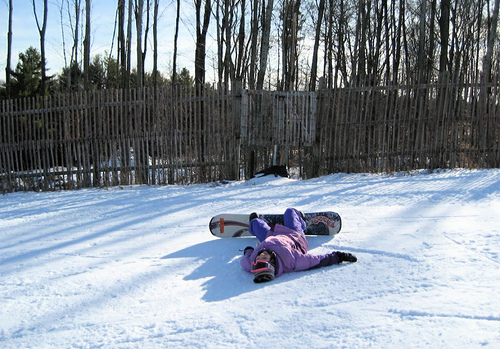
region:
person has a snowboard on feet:
[201, 196, 362, 286]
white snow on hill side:
[120, 249, 134, 270]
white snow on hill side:
[421, 276, 496, 334]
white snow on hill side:
[387, 203, 415, 217]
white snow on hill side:
[45, 278, 72, 299]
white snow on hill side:
[377, 309, 425, 343]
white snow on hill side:
[400, 209, 432, 241]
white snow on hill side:
[122, 292, 146, 323]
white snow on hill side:
[284, 305, 311, 333]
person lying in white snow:
[180, 211, 372, 283]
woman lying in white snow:
[182, 192, 354, 282]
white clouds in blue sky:
[32, 20, 58, 44]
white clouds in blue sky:
[181, 20, 208, 53]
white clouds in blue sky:
[272, 9, 303, 51]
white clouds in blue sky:
[368, 19, 401, 56]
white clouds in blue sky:
[445, 5, 475, 28]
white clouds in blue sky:
[275, 31, 292, 53]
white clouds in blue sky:
[281, 25, 324, 68]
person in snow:
[210, 201, 353, 276]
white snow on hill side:
[17, 248, 49, 293]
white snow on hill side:
[387, 281, 429, 328]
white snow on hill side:
[274, 285, 301, 321]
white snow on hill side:
[424, 190, 488, 243]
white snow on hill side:
[366, 190, 406, 224]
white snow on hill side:
[122, 222, 171, 256]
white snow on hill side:
[40, 229, 108, 261]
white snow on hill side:
[98, 237, 140, 262]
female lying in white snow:
[193, 195, 350, 276]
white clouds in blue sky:
[13, 13, 45, 43]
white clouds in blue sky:
[42, 9, 82, 46]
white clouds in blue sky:
[113, 11, 193, 53]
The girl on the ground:
[236, 206, 357, 321]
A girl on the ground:
[226, 211, 357, 294]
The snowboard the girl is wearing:
[200, 209, 346, 241]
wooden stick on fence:
[130, 88, 142, 187]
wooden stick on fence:
[139, 86, 148, 184]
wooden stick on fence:
[196, 81, 206, 174]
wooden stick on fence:
[209, 81, 220, 178]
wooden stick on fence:
[11, 97, 35, 189]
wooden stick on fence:
[42, 93, 57, 190]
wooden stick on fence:
[234, 82, 244, 178]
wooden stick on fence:
[353, 78, 362, 170]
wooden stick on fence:
[430, 68, 441, 163]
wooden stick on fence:
[457, 73, 467, 169]